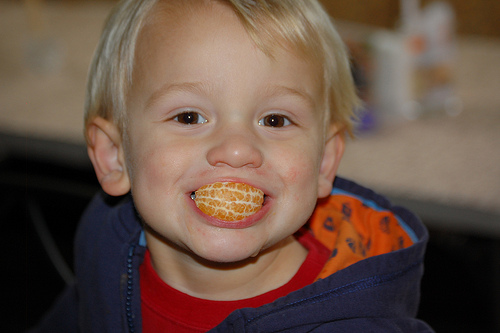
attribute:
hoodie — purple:
[32, 177, 439, 332]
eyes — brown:
[155, 104, 315, 136]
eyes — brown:
[168, 108, 294, 127]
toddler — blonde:
[32, 0, 431, 332]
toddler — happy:
[53, 5, 440, 326]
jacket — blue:
[26, 178, 433, 330]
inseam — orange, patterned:
[306, 192, 411, 282]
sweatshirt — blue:
[40, 179, 437, 331]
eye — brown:
[174, 112, 202, 124]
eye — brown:
[260, 115, 291, 126]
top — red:
[132, 245, 327, 324]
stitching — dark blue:
[278, 272, 384, 307]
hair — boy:
[82, 2, 372, 147]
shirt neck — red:
[134, 242, 328, 312]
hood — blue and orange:
[272, 173, 432, 331]